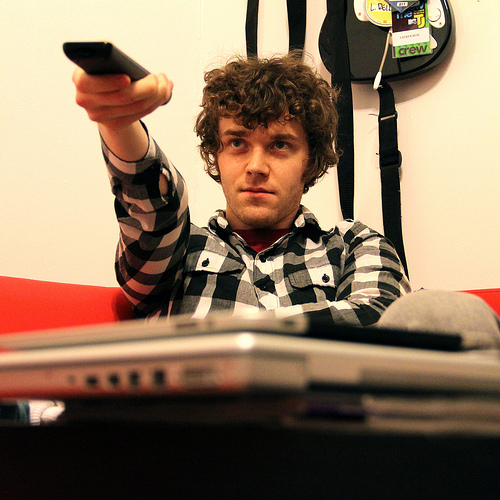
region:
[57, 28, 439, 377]
man holding a remote control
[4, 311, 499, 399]
silver laptop that is closed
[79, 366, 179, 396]
black holes on the side of the laptop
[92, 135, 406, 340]
white, black, and gray shirt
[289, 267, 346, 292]
pocket on the shirt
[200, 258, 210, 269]
black button on the pocket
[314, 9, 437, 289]
black strap hanging down the wall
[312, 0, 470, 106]
black guitar hanging on the wall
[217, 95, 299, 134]
hair laying on the forehead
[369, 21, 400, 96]
silver and white bar hanging off the guitar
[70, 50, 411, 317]
man sitting and using remote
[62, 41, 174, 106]
a black remote in the man's hand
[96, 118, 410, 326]
black and white checkered shirt on the man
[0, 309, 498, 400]
a closed laptop computer in front of the man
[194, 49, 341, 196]
brown, curly hair on man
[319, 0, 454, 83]
black electric guitar hanging on wall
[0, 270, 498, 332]
a red couch under the man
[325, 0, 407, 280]
a black strap on the guitar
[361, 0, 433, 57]
papers on the guitar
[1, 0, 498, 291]
white wall behind the man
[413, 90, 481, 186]
this is the wall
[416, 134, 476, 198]
the wall is white in color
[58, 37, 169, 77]
this is a remote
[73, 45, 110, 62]
the remote is black in color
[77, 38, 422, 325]
this is a man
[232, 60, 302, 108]
the hair is long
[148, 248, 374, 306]
this is a shirt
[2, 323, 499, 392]
this is a laptop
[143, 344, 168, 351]
the laptop is grey in color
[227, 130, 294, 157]
these are the eyes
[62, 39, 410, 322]
a man pointing a remote control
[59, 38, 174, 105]
a black tv remote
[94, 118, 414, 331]
a man with black and white shirt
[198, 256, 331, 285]
two black buttons on man's shirt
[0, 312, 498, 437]
a black and gray laptop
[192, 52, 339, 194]
a man with brown hair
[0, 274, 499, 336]
a bright orange sofa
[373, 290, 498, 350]
part of the man gray pants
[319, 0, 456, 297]
a black carrier with strap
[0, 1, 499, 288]
a off white wall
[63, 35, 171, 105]
The remote in the man's hand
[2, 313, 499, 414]
The silver laptop in front of the man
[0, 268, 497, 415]
Red couch the man is sitting on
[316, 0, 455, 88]
Guitar hanging on the wall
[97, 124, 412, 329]
The man's flannel shirt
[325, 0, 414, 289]
The strap connected to the guitar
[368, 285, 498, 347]
The portion of grey pants shown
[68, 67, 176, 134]
The hand holding the remote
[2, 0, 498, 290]
The white wall behind the couch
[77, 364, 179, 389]
Open ports on the side of the computer